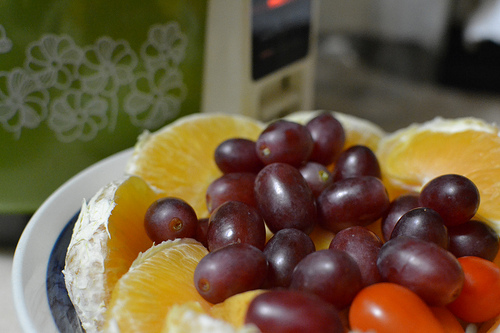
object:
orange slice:
[62, 173, 172, 332]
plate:
[10, 140, 151, 331]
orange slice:
[103, 238, 210, 331]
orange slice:
[123, 113, 266, 218]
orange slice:
[270, 110, 385, 176]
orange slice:
[375, 113, 499, 234]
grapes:
[143, 195, 200, 244]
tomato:
[349, 282, 442, 332]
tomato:
[448, 255, 500, 323]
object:
[0, 1, 207, 215]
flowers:
[44, 88, 110, 144]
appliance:
[199, 0, 319, 128]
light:
[267, 0, 289, 8]